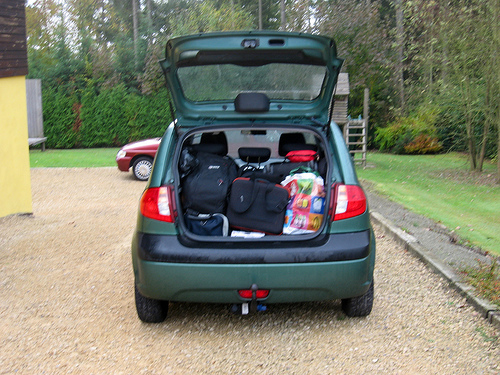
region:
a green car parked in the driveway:
[131, 28, 376, 323]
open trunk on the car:
[159, 31, 343, 243]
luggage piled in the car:
[181, 149, 328, 239]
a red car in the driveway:
[116, 136, 163, 182]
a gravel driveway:
[1, 165, 498, 374]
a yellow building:
[0, 0, 35, 219]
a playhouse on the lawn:
[312, 73, 369, 168]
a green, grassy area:
[27, 147, 499, 260]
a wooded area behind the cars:
[25, 0, 499, 158]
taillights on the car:
[138, 180, 368, 220]